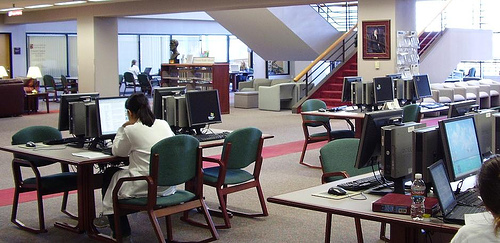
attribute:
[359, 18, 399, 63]
picture — framed, wood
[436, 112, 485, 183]
computer monitor — large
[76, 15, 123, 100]
pole — large, white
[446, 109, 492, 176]
screen — on, computer screen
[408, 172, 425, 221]
water bottle — tall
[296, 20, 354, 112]
stair railing — brown, wooden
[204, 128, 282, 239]
chair — wooden, green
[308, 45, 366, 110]
stairway — red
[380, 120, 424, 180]
monitor — black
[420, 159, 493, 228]
computer — small, black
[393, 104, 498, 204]
hot computer — small, black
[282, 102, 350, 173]
chair — wooden, green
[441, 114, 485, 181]
computer screen — turned on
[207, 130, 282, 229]
chair — wood, green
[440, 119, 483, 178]
monitor — small, black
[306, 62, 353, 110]
staircase — red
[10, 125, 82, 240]
chair — green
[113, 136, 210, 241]
chair — wooden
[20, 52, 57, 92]
lamp — bright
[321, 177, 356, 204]
computer mouse — black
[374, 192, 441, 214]
notebook — red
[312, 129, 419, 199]
chair — green, wooden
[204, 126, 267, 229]
chair — green, brown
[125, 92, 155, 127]
hair — black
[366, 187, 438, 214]
book — closed, red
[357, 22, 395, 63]
photo wall — framed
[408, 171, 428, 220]
water — bottled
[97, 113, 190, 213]
coat — white